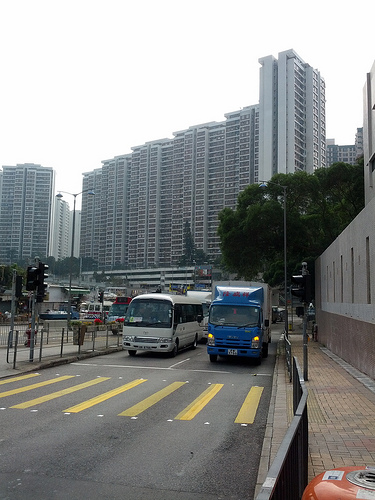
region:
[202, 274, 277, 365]
truck on the right is blue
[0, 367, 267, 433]
pedestrian walk has yellow lines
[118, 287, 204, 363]
bus on left is white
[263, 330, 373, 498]
sidewalk is made from bricks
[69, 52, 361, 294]
large building in background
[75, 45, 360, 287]
the large building is white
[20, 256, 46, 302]
traffic lights are on pole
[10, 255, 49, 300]
traffic light covers are black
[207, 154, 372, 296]
trees are behind wall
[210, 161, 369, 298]
the trees are green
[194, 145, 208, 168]
windows in a building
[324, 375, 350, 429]
a bricked sidewalk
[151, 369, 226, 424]
yellow painted crosswalk lines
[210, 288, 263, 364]
the front of a truck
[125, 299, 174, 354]
the front of a bus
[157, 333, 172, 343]
a headlight on a vehicle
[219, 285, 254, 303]
writing on a truck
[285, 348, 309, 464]
metal barriers on a sidewalk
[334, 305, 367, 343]
the wall of a building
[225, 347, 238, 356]
license plate on a vehicle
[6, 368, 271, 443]
yellow road lines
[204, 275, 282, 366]
blue truck on the road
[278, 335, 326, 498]
black railing near the road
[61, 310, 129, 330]
flowers near the road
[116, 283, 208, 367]
white van next to the blue truck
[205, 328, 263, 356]
lights on the blue truck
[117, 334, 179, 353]
lights on the white van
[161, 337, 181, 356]
wheel on the white van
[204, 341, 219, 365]
wheel on the blue truck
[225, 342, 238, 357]
license plate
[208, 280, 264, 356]
this is a lorry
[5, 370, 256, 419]
yellow strips are on the road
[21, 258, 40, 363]
the street light is beside the road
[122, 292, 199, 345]
this is a white bus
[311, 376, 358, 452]
the pavement is made of arranged bricks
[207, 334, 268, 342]
the front lights are on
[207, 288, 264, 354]
the lorry is blue in color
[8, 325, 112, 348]
the metal grills are beside the road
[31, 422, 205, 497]
the road is made of tamarc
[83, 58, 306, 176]
the buildings are arranged in a column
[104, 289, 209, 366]
a bus on a street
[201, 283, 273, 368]
a blue truck on a street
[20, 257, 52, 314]
traffic signal on a pole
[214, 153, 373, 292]
trees next to a building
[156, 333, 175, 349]
front headlight of a vehicle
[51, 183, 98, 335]
a light pole on a street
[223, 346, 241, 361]
a licence plate on the front of a vehicle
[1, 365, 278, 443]
yellow markings on a street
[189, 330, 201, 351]
the wheel of a vehicle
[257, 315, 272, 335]
side rear view mirror of a vehicle